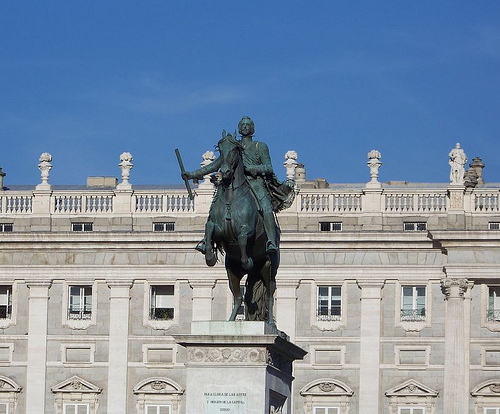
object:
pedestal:
[169, 315, 303, 411]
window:
[137, 277, 192, 333]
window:
[392, 276, 431, 331]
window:
[477, 278, 498, 327]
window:
[227, 281, 248, 317]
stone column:
[439, 275, 474, 413]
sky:
[7, 7, 488, 108]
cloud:
[167, 72, 257, 109]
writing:
[183, 359, 268, 411]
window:
[67, 285, 96, 317]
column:
[341, 129, 395, 411]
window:
[313, 279, 343, 321]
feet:
[199, 245, 220, 265]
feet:
[238, 253, 254, 269]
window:
[309, 282, 351, 326]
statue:
[174, 115, 294, 323]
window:
[316, 213, 347, 233]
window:
[483, 213, 498, 227]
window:
[404, 209, 429, 234]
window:
[146, 216, 186, 235]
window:
[67, 220, 95, 236]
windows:
[300, 248, 447, 333]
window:
[311, 403, 341, 412]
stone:
[300, 377, 352, 395]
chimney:
[468, 156, 484, 183]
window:
[0, 287, 13, 324]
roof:
[4, 143, 493, 235]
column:
[168, 334, 297, 412]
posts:
[18, 134, 487, 185]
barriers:
[9, 193, 499, 213]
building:
[0, 140, 498, 410]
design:
[4, 338, 499, 376]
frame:
[307, 280, 348, 329]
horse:
[194, 134, 284, 323]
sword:
[172, 146, 197, 203]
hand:
[177, 168, 196, 187]